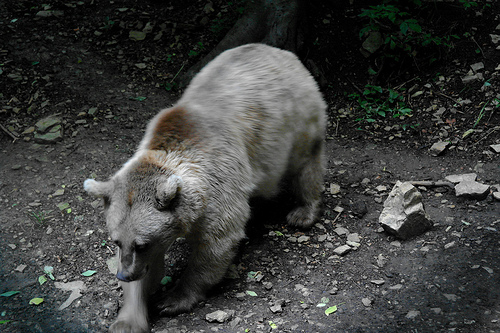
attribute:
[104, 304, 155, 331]
bear paw — furry , brown , large 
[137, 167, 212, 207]
ear — large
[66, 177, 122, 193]
ear — furry, large, bear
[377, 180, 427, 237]
rock — large, jagged, grey